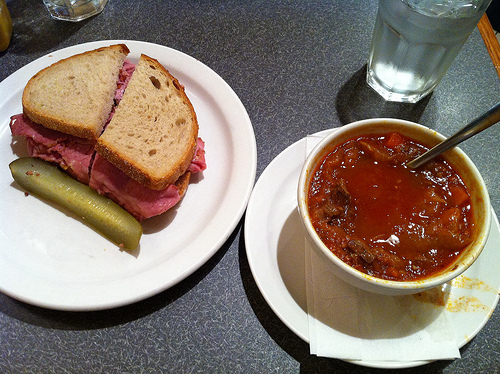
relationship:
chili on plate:
[446, 276, 484, 307] [245, 124, 484, 370]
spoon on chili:
[417, 96, 498, 168] [310, 125, 480, 281]